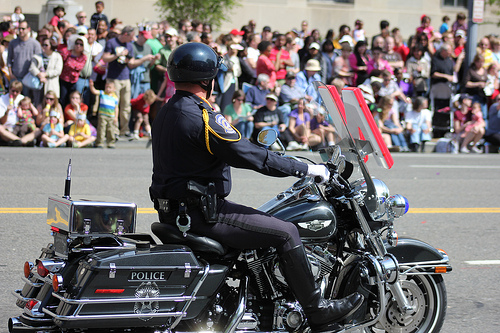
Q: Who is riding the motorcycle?
A: A police officer.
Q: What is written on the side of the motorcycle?
A: "Police".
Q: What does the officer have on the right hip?
A: A handgun.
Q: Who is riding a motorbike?
A: Police officer.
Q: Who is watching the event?
A: Spectators.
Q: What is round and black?
A: Tires.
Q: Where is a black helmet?
A: On officer's head.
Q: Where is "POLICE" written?
A: On side of the bike.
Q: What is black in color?
A: Officer's uniform.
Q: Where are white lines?
A: On the pavement.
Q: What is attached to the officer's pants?
A: Handcuffs.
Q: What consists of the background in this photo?
A: Lots of people.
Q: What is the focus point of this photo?
A: Police officer riding motorcycle.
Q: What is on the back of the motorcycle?
A: Radio antenna.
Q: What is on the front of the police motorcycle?
A: A blue light.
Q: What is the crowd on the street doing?
A: Watching parade.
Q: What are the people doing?
A: Watching the parade.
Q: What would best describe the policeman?
A: On a motorcycle.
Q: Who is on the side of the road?
A: A crowd watching a parade.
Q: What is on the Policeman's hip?
A: Handcuffs and a gun.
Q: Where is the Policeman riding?
A: On the street.